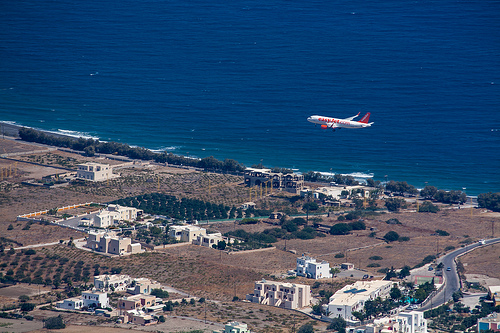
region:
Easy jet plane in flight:
[305, 108, 375, 133]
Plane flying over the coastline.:
[0, 0, 496, 195]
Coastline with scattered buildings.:
[0, 132, 496, 194]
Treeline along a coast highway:
[0, 125, 210, 161]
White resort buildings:
[80, 202, 140, 222]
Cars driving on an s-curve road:
[415, 235, 495, 312]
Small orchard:
[115, 192, 246, 217]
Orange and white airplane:
[305, 110, 371, 130]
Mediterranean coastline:
[72, 101, 248, 162]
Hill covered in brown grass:
[151, 250, 256, 286]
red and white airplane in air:
[301, 97, 373, 152]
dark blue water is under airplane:
[250, 35, 356, 106]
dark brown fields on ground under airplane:
[323, 221, 476, 252]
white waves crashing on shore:
[105, 120, 410, 180]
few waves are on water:
[122, 43, 253, 122]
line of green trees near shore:
[133, 160, 468, 207]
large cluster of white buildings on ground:
[70, 200, 214, 267]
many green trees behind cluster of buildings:
[130, 185, 227, 240]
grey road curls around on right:
[408, 223, 490, 310]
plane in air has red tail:
[353, 107, 378, 127]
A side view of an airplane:
[285, 91, 386, 156]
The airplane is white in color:
[290, 95, 385, 150]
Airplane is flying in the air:
[296, 90, 386, 152]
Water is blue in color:
[3, 4, 499, 189]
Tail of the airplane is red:
[354, 108, 376, 126]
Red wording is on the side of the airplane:
[313, 111, 345, 129]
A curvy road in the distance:
[404, 220, 499, 321]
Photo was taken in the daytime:
[6, 5, 496, 325]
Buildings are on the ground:
[57, 157, 437, 330]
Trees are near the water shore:
[17, 115, 246, 194]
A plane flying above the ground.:
[297, 95, 398, 138]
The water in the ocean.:
[0, 0, 495, 200]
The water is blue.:
[61, 26, 469, 79]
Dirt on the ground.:
[390, 243, 420, 258]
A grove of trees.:
[112, 186, 257, 221]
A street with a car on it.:
[403, 221, 498, 331]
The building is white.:
[287, 245, 335, 281]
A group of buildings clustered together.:
[45, 266, 180, 326]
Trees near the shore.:
[10, 116, 266, 169]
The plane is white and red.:
[302, 106, 385, 136]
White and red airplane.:
[305, 110, 377, 132]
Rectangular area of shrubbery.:
[103, 188, 249, 227]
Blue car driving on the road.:
[442, 265, 452, 271]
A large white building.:
[71, 160, 116, 182]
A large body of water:
[0, 0, 498, 207]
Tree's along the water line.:
[385, 183, 467, 206]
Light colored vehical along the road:
[476, 237, 487, 245]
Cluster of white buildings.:
[74, 199, 232, 261]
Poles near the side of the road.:
[431, 230, 441, 266]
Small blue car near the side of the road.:
[425, 266, 434, 272]